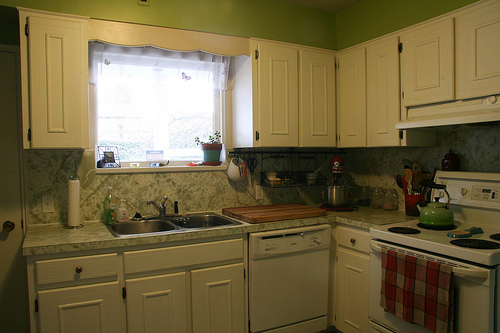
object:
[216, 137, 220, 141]
flowers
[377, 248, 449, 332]
towel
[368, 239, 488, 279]
door handle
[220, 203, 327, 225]
board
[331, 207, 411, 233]
top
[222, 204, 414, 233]
counter top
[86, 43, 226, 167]
window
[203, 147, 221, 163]
paint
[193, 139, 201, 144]
flowers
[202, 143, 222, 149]
paint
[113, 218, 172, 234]
inside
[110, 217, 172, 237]
sink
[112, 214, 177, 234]
left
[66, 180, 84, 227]
towel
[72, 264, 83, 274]
knob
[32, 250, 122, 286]
drawer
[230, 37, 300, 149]
cabinets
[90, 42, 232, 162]
curtain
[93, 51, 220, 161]
light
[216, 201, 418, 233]
counter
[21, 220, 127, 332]
cabinets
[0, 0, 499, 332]
kitchen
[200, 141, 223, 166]
vase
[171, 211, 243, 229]
sink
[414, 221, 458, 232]
burner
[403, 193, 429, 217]
utensil holder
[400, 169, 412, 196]
utensils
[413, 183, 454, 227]
kettle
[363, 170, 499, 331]
stove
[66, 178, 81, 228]
paper towels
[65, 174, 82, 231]
holder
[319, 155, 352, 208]
mixer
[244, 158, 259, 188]
scissors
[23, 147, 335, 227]
wall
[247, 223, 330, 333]
dishwasher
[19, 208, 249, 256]
kitchen counter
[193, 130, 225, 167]
plant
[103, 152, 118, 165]
picture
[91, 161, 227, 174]
window sill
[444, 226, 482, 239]
spoon holder